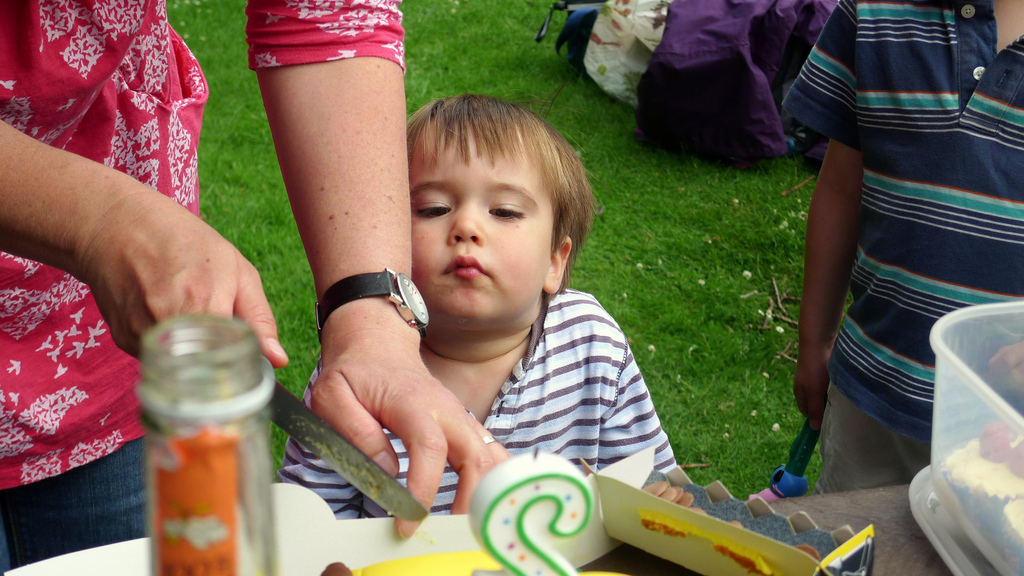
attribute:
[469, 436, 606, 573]
number candle — white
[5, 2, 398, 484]
shirt — red, white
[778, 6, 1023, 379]
shirt — blue, striped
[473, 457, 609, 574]
trim — green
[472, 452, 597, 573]
candle — green, white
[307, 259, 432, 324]
wristwatch — black, gray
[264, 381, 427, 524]
butter knife — gray, long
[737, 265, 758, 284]
flower — white, small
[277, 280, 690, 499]
shirt — white, blue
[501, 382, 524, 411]
button — white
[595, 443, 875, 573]
cardboard box — white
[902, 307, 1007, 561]
plastic container — large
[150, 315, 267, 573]
jar — tall, glass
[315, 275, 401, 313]
band — black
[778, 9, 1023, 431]
shirt — blue, short sleeved, stripes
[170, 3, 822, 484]
grass — lush, green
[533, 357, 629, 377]
stripe — brown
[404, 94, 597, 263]
hair — short, cut , brown, light brown